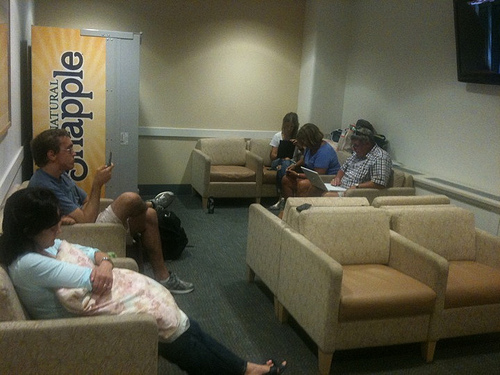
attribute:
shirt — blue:
[28, 164, 88, 223]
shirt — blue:
[6, 236, 106, 322]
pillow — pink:
[55, 237, 190, 343]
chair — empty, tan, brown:
[279, 203, 444, 363]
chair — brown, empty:
[384, 202, 499, 363]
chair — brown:
[241, 194, 373, 315]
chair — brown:
[191, 135, 262, 214]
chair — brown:
[373, 195, 453, 207]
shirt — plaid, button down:
[338, 142, 395, 200]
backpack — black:
[135, 203, 192, 262]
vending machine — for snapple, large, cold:
[26, 21, 144, 205]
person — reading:
[267, 112, 300, 214]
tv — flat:
[452, 1, 500, 89]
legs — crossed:
[93, 188, 197, 295]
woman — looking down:
[281, 119, 341, 214]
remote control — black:
[295, 200, 313, 219]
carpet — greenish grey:
[1, 180, 500, 373]